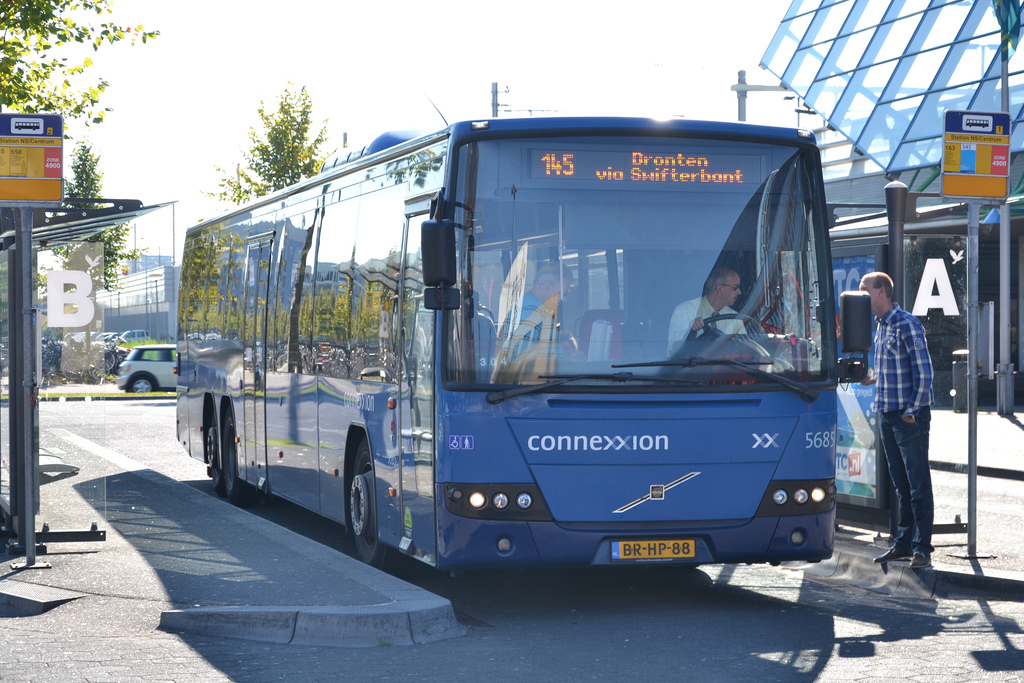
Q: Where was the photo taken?
A: At a bus stop.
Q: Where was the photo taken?
A: At a bus stop in a city.